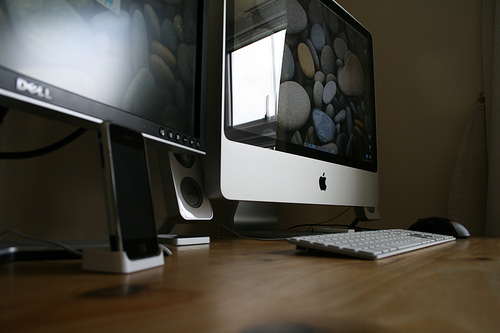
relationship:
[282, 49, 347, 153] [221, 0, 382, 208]
rocks on apple monitor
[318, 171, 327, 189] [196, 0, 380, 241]
apple logo on monitor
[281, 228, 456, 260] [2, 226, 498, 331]
computer keyboard on desk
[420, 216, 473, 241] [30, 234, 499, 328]
computer mouse on desk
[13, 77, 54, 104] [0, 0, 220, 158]
lettering on monitor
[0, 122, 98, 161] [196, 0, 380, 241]
cord on monitor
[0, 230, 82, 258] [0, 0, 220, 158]
cord on monitor